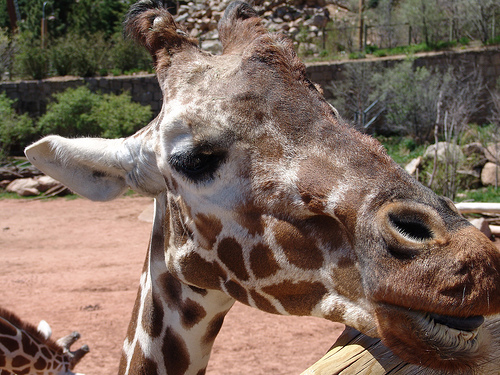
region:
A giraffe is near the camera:
[22, 3, 494, 374]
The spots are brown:
[193, 214, 310, 309]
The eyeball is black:
[185, 149, 214, 176]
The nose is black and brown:
[376, 199, 446, 252]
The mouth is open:
[377, 294, 499, 331]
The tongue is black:
[430, 311, 485, 334]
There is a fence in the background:
[300, 14, 498, 55]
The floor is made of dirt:
[17, 219, 117, 286]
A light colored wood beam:
[302, 335, 387, 374]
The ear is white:
[25, 134, 156, 201]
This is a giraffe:
[79, 20, 496, 341]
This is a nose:
[345, 198, 442, 250]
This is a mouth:
[367, 248, 496, 372]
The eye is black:
[148, 125, 255, 199]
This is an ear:
[7, 126, 142, 225]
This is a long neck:
[110, 257, 217, 345]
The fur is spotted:
[117, 192, 267, 313]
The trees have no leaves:
[407, 57, 496, 138]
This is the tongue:
[425, 300, 480, 326]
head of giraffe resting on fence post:
[19, 14, 461, 364]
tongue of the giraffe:
[437, 315, 481, 330]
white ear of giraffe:
[30, 118, 135, 197]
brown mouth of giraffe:
[368, 229, 496, 361]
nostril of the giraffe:
[362, 192, 450, 251]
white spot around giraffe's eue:
[156, 108, 245, 212]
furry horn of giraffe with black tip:
[117, 3, 197, 73]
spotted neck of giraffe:
[99, 284, 229, 373]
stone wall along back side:
[8, 54, 499, 152]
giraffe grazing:
[2, 299, 87, 371]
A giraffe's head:
[18, 0, 498, 367]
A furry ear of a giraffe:
[20, 115, 156, 204]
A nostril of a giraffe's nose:
[374, 196, 445, 250]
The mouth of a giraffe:
[347, 245, 498, 356]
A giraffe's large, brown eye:
[157, 136, 235, 189]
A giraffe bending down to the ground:
[0, 308, 100, 373]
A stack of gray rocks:
[400, 134, 498, 193]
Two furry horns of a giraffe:
[120, 0, 292, 85]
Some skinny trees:
[421, 64, 471, 202]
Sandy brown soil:
[0, 198, 357, 373]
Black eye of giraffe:
[153, 136, 233, 182]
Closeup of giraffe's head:
[26, 7, 496, 364]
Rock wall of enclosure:
[301, 43, 496, 129]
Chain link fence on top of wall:
[296, 18, 495, 58]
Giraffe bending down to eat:
[1, 295, 95, 374]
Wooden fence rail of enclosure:
[284, 317, 499, 373]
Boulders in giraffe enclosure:
[405, 137, 499, 192]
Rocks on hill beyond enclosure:
[165, 1, 328, 57]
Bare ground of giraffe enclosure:
[8, 205, 134, 335]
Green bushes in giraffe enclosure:
[5, 78, 162, 143]